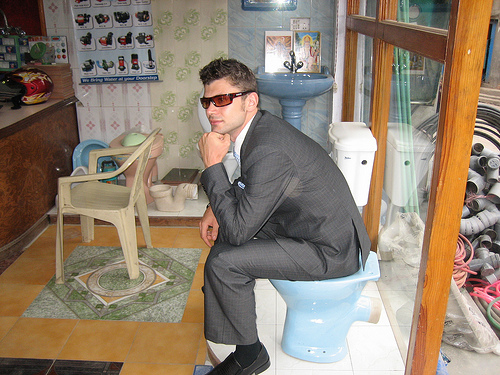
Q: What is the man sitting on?
A: Toilet.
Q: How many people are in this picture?
A: 1.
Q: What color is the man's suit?
A: Grey.